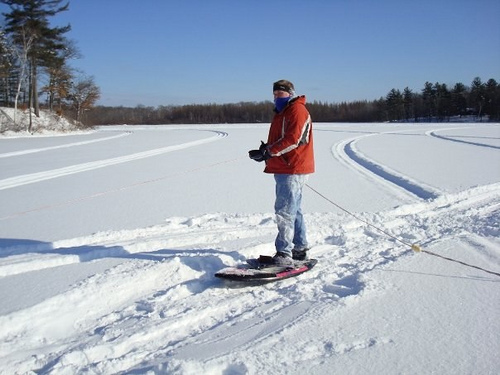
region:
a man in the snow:
[224, 71, 367, 298]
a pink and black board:
[220, 242, 335, 304]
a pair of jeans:
[256, 152, 321, 258]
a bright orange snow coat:
[243, 95, 331, 187]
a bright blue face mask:
[267, 86, 299, 113]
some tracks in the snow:
[323, 94, 478, 274]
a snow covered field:
[58, 95, 484, 327]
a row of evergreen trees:
[379, 66, 493, 123]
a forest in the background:
[87, 91, 392, 140]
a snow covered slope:
[0, 101, 94, 145]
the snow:
[369, 270, 474, 366]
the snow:
[222, 323, 289, 369]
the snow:
[202, 292, 274, 362]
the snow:
[293, 327, 355, 365]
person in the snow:
[211, 81, 349, 291]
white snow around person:
[76, 206, 198, 321]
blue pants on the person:
[261, 172, 321, 234]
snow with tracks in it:
[124, 252, 207, 329]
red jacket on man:
[257, 105, 327, 173]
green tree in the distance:
[13, 6, 105, 89]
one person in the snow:
[200, 65, 387, 282]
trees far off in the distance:
[388, 76, 467, 118]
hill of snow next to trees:
[14, 103, 65, 135]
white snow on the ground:
[131, 130, 231, 227]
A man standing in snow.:
[249, 78, 314, 270]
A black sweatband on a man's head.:
[270, 80, 293, 91]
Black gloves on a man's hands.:
[247, 141, 268, 162]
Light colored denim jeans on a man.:
[268, 170, 310, 256]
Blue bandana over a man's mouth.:
[270, 96, 292, 113]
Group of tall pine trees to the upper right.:
[384, 75, 499, 120]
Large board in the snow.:
[210, 250, 319, 285]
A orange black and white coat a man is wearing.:
[262, 94, 314, 176]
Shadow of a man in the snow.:
[2, 234, 252, 273]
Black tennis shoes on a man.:
[265, 246, 307, 270]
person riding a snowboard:
[205, 68, 348, 300]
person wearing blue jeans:
[227, 80, 334, 290]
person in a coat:
[246, 75, 330, 190]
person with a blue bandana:
[229, 65, 344, 201]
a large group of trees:
[0, 1, 113, 131]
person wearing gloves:
[201, 61, 348, 303]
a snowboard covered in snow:
[183, 239, 338, 299]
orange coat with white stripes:
[246, 91, 323, 184]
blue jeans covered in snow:
[258, 168, 323, 270]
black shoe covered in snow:
[248, 243, 300, 277]